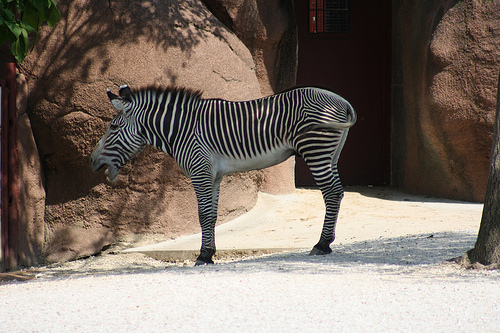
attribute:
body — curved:
[75, 78, 361, 263]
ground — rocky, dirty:
[1, 188, 495, 333]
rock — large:
[391, 2, 499, 199]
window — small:
[308, 2, 341, 31]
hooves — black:
[190, 251, 328, 259]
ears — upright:
[103, 83, 134, 112]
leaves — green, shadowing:
[3, 1, 66, 55]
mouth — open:
[91, 159, 118, 181]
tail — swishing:
[295, 104, 358, 134]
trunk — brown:
[464, 147, 500, 272]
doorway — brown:
[285, 1, 392, 188]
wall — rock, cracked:
[8, 2, 286, 255]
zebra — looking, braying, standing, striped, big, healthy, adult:
[92, 86, 354, 263]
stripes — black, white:
[173, 106, 321, 147]